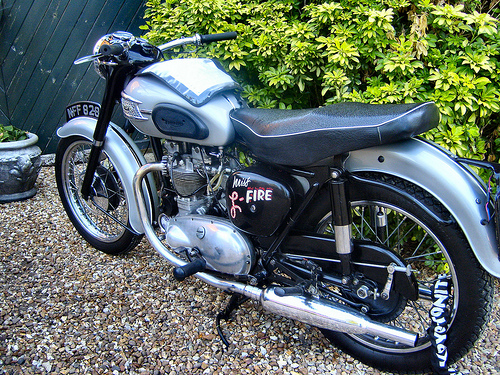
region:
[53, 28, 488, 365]
a grey and black motorcycle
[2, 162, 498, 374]
a gravel driveway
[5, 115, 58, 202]
a potted plant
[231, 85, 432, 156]
a grey padded seat on a motorcycle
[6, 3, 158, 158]
a dark green painted fence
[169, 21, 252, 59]
a handlebar on a motorcyce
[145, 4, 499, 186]
a green tree next to a motorcycle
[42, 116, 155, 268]
the front wheel of a motorcycle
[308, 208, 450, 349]
spokes on a wheel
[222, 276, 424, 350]
a silver colored exhaust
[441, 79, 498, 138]
these are several leaves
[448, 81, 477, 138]
the leaves are green in color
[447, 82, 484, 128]
the leaves are small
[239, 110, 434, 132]
this is a motorcycle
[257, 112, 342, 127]
the seat is black in color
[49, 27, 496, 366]
this is a motorcycle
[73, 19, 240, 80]
this is the steering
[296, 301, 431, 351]
this is an exhaust pipe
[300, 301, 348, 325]
the exhaust pipe is shiny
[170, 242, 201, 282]
this is a pedal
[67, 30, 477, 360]
this is a motorbike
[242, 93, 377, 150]
this is a seat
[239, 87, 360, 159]
the seat is leather like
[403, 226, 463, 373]
the wheel is black in color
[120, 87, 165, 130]
the motorbike is grey in color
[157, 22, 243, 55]
this is a steering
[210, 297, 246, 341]
this is a stand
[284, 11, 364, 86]
the leaves are green in color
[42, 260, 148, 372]
the stones are small in size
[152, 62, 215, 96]
this is a mat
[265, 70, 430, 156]
black seat of bike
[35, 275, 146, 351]
many different rocks next to bike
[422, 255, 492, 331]
black wheel of bike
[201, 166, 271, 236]
words on side of bike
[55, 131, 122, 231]
front tire of bike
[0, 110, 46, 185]
gray flower pot next to bike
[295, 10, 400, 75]
green leaves next to bike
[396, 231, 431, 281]
spokes of the bike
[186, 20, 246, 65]
black handlebar of bike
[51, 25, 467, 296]
a black and silver bike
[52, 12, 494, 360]
a silver and black motorcycle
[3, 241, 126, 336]
A gravel drive way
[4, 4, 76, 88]
blue diagonal wood siding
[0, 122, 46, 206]
a ceramic planter with foliage in it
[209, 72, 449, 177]
a seat large enough for two people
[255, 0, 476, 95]
green plants in the background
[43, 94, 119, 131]
an identification number of WFF828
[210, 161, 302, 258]
the motorcyle is named L-Fire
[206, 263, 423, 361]
a silver muffler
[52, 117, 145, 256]
a black wheel with spokes